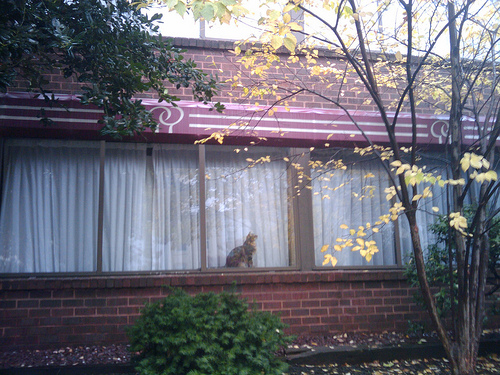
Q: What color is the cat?
A: Brown.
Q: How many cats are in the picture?
A: One.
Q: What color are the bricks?
A: Red.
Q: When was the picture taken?
A: During the day.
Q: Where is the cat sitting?
A: On the window seal.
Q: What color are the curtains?
A: White.